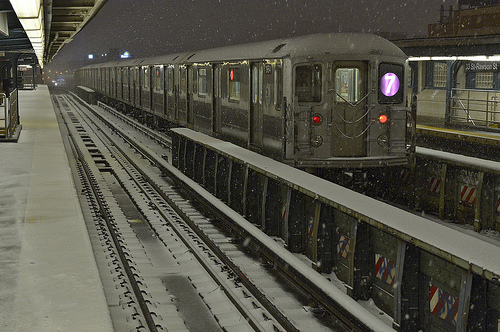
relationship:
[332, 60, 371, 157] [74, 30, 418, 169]
door to train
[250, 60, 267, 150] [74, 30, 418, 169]
door to train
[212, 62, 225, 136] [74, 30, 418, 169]
door to train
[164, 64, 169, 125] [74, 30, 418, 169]
door to train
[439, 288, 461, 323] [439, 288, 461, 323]
graffiti has graffiti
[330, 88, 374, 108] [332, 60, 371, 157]
rope covers door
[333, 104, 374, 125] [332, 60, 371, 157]
rope covers door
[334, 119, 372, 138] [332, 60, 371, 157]
rope covers door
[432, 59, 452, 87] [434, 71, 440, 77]
window has block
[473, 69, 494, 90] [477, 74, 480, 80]
window has block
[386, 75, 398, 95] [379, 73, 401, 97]
number in circle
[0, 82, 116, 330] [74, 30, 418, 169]
platform beside train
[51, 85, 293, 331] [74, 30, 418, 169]
track beside train